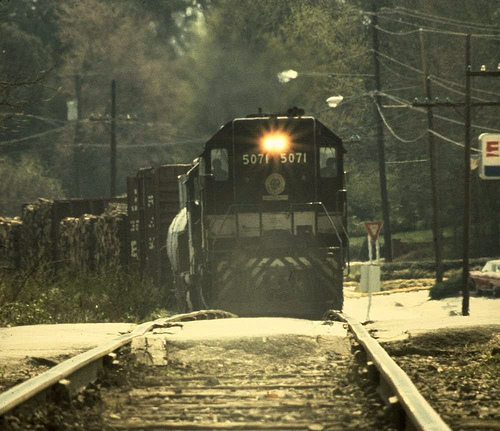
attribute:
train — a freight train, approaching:
[1, 106, 351, 317]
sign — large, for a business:
[478, 133, 500, 183]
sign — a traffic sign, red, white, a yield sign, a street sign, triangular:
[362, 220, 385, 243]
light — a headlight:
[258, 131, 293, 156]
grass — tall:
[2, 251, 180, 323]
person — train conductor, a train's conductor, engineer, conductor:
[211, 158, 228, 181]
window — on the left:
[210, 147, 231, 185]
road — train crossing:
[2, 294, 494, 354]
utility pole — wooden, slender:
[72, 73, 79, 202]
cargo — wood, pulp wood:
[56, 203, 126, 284]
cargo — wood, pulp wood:
[23, 199, 55, 291]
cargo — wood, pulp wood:
[1, 215, 18, 281]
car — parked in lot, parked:
[467, 259, 500, 298]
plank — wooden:
[123, 384, 337, 398]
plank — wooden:
[104, 419, 365, 430]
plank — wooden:
[146, 400, 348, 412]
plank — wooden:
[129, 336, 168, 367]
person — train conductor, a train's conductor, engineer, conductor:
[320, 155, 339, 178]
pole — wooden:
[108, 77, 116, 200]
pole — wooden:
[371, 6, 397, 252]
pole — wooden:
[427, 76, 443, 288]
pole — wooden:
[460, 32, 474, 318]